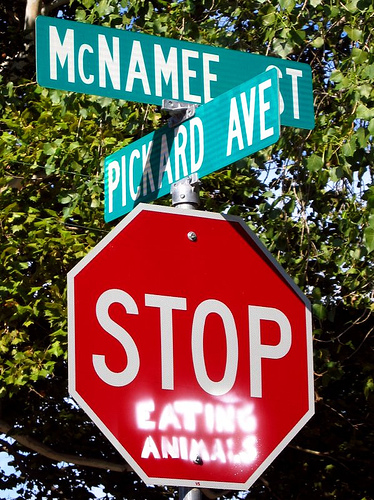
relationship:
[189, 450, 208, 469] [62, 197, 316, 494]
screw connecting sign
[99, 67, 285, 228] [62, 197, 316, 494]
sign above sign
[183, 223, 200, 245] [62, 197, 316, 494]
bolt in sign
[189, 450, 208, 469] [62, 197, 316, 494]
screw in sign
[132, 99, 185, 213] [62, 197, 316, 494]
shadow on sign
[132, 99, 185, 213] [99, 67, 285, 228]
shadow on sign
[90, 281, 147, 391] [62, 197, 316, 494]
letter on front of sign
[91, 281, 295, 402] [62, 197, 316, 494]
letters on sign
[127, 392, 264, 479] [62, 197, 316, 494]
hand writing on sign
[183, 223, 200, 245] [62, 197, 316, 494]
bolt on sign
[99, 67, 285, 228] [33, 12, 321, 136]
sign on top of sign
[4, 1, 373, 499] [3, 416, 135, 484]
tree has limb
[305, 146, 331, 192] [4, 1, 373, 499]
leaf on a tree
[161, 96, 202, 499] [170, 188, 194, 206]
pole has part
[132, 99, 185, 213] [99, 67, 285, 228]
shadow on a sign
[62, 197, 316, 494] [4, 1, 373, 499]
sign in front of tree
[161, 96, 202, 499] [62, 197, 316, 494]
pole supporting sign